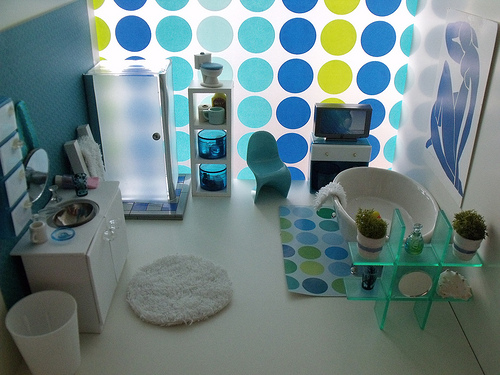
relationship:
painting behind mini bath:
[412, 22, 488, 193] [332, 166, 440, 245]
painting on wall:
[412, 22, 488, 193] [407, 3, 498, 220]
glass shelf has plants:
[352, 254, 442, 329] [351, 206, 388, 261]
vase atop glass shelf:
[403, 222, 425, 257] [343, 208, 483, 330]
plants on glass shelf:
[355, 216, 401, 265] [343, 208, 483, 330]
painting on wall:
[422, 6, 499, 208] [398, 0, 498, 345]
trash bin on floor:
[4, 290, 81, 374] [0, 170, 485, 373]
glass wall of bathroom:
[227, 10, 304, 115] [0, 0, 499, 372]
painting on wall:
[422, 6, 499, 208] [394, 0, 498, 372]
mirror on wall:
[21, 143, 59, 193] [0, 0, 95, 374]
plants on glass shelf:
[353, 199, 487, 293] [343, 208, 483, 330]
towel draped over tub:
[310, 181, 349, 211] [326, 160, 438, 249]